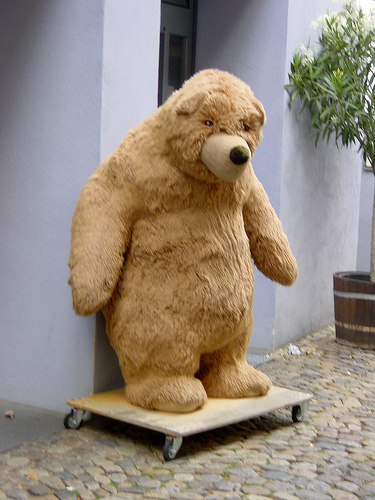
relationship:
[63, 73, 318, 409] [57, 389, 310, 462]
bear on a wheelie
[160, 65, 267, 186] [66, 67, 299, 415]
head on a bear